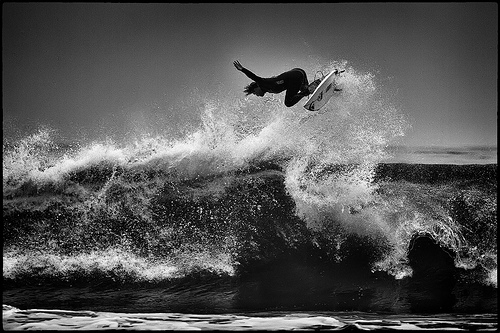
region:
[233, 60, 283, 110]
the head of a man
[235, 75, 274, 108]
the hair of a man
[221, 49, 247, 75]
the hand of a man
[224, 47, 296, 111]
the arm of a man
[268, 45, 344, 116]
the legs of a man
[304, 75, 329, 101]
the foot of a man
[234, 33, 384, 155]
a man on a surfboard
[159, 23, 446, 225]
a man riding a wave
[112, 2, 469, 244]
a wave in the ocean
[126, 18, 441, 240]
a man in the ocean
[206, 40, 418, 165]
the surfer is in the air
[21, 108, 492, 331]
the wave is beginning to close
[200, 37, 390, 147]
this person is on a shortboard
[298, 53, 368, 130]
a white surfboard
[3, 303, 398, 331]
white sea foam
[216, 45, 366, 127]
the surfer is wearing a black wet suit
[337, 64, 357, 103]
the fins of the surfboard are black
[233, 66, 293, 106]
the surfer has long hair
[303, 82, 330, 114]
a black logo on the bottom of the surfboard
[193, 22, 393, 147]
the surfer jumped into the air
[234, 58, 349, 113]
The man is surfing.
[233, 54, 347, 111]
The man is in the air.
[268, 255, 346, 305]
The water is dark in color.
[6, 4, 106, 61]
The sky is dark in color.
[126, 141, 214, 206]
The ocean wave is white.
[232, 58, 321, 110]
The man is wearing a black wet suit.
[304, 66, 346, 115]
The surfboard is white.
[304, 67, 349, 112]
The surfboard has fins.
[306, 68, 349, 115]
The surfboard has black symbols.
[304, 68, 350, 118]
The surfboard has a point.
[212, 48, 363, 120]
person on a surboard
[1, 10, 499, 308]
person surfing a wave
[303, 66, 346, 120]
surfboard in the water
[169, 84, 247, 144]
water coming off the wave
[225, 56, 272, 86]
hand is up in the air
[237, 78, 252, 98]
hair is blowing around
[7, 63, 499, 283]
wave in the water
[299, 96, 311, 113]
pointy tip of the surfboard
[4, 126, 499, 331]
body of water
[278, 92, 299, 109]
knee is bent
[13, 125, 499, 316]
the seawater has a high wave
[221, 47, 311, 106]
a person in the air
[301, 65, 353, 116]
a surboard in the air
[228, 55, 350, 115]
the person is surfboarding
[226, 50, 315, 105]
the person has their arm in the air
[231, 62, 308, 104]
the person is wearing a wetsuit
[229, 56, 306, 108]
the wetsuit is black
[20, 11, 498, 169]
the sky is clear and calm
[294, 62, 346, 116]
the surfboard is white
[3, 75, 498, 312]
the waves are making splashes